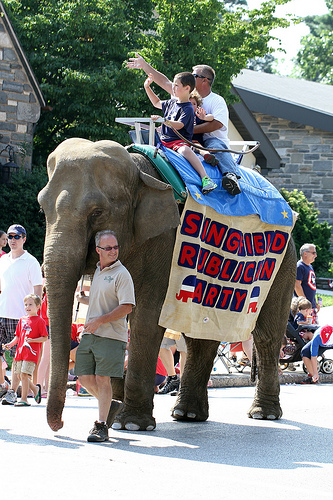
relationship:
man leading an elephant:
[74, 227, 137, 444] [30, 138, 299, 431]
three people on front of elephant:
[126, 52, 243, 194] [30, 138, 299, 431]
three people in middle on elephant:
[126, 52, 243, 194] [30, 138, 299, 431]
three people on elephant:
[126, 52, 243, 194] [30, 138, 299, 431]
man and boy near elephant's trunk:
[0, 223, 49, 407] [42, 234, 90, 432]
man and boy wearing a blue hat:
[0, 223, 49, 407] [8, 224, 25, 237]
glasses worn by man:
[97, 244, 120, 252] [74, 227, 137, 444]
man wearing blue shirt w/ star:
[294, 241, 320, 326] [293, 260, 319, 309]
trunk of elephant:
[42, 234, 90, 432] [30, 138, 299, 431]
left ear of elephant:
[130, 168, 182, 249] [30, 138, 299, 431]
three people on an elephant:
[128, 52, 242, 194] [30, 138, 299, 431]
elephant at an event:
[30, 138, 299, 431] [0, 51, 333, 498]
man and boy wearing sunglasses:
[0, 223, 49, 407] [6, 234, 25, 241]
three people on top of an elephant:
[126, 52, 243, 194] [30, 138, 299, 431]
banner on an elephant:
[157, 147, 299, 344] [30, 138, 299, 431]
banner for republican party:
[157, 147, 299, 344] [174, 241, 276, 312]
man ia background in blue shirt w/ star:
[294, 241, 320, 326] [293, 260, 319, 309]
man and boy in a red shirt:
[0, 223, 49, 407] [14, 314, 47, 364]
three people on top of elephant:
[128, 52, 242, 194] [30, 138, 299, 431]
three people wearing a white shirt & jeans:
[126, 52, 243, 194] [197, 90, 243, 178]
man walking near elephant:
[74, 227, 137, 444] [30, 138, 299, 431]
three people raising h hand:
[126, 52, 243, 194] [144, 72, 155, 88]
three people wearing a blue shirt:
[126, 52, 243, 194] [159, 99, 194, 141]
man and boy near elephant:
[0, 225, 50, 407] [30, 138, 299, 431]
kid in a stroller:
[293, 300, 315, 327] [279, 309, 333, 373]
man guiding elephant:
[74, 227, 137, 444] [30, 138, 299, 431]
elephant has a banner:
[30, 138, 299, 431] [157, 147, 299, 344]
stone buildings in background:
[0, 0, 333, 225] [1, 0, 333, 429]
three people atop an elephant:
[128, 52, 242, 194] [30, 138, 299, 431]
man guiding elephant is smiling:
[74, 227, 137, 444] [107, 250, 119, 260]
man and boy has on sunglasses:
[0, 223, 49, 407] [6, 234, 25, 241]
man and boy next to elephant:
[0, 223, 49, 407] [30, 138, 299, 431]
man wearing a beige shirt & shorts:
[74, 227, 137, 444] [72, 258, 137, 376]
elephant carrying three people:
[30, 138, 299, 431] [128, 52, 242, 194]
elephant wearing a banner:
[30, 138, 299, 431] [157, 147, 299, 344]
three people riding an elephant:
[126, 52, 243, 194] [30, 138, 299, 431]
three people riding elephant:
[126, 52, 243, 194] [30, 138, 299, 431]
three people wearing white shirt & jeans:
[126, 52, 243, 194] [197, 90, 243, 178]